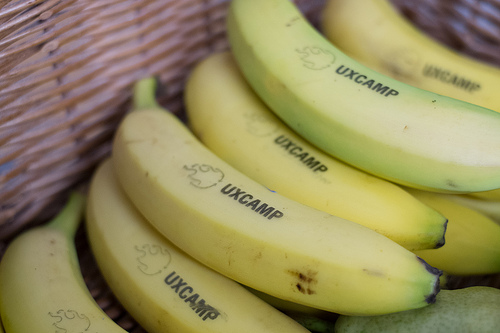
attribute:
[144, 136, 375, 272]
banana — yellow, laying, greenish, fruit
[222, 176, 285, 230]
lettering — black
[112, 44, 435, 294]
bananas — yellow, 3, 7, lying, ripe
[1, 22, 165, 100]
basket — brown, wicker, woven, pink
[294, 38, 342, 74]
design — black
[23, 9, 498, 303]
scene — outdoor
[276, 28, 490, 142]
banana — green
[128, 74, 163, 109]
stem — green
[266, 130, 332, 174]
stamps — black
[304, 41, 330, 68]
symbol — small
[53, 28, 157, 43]
grooves — pink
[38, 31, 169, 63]
lines — black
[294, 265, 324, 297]
spots — brown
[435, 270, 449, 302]
tip — black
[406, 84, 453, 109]
spot — green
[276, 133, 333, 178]
words — black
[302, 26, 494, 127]
edge — green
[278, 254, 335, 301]
bruising — black, small